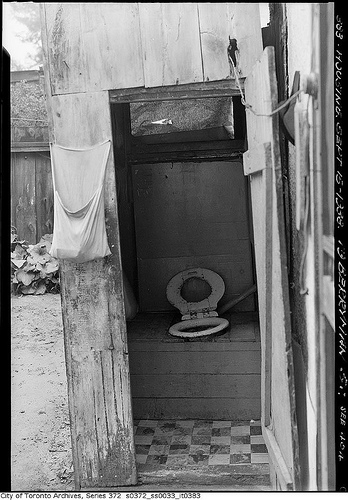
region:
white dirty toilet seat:
[157, 266, 236, 344]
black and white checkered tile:
[139, 416, 267, 469]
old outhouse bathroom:
[33, 4, 312, 490]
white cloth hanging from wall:
[43, 131, 128, 269]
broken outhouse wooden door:
[216, 42, 327, 484]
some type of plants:
[13, 235, 63, 298]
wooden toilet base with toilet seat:
[138, 308, 249, 428]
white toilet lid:
[163, 259, 231, 309]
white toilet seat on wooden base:
[164, 318, 236, 342]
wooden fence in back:
[11, 142, 56, 252]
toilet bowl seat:
[164, 269, 233, 341]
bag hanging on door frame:
[42, 130, 110, 261]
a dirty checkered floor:
[139, 415, 247, 452]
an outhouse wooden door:
[233, 48, 305, 483]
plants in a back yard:
[11, 231, 55, 293]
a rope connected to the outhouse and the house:
[223, 41, 310, 118]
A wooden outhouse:
[29, 6, 320, 496]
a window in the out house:
[125, 94, 236, 144]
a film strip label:
[333, 5, 342, 282]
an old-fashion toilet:
[129, 260, 263, 422]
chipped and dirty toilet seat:
[165, 266, 230, 338]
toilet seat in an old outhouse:
[164, 267, 226, 334]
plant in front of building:
[8, 227, 55, 294]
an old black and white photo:
[2, 3, 335, 490]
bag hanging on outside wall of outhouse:
[47, 136, 109, 260]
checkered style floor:
[132, 418, 267, 470]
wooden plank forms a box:
[134, 310, 258, 418]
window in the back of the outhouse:
[110, 94, 239, 137]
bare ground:
[9, 291, 71, 487]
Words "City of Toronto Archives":
[1, 490, 85, 497]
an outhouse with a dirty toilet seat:
[39, 159, 301, 384]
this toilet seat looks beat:
[157, 268, 238, 342]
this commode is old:
[77, 272, 320, 461]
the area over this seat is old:
[107, 71, 271, 168]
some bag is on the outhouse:
[35, 124, 136, 267]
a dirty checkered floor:
[123, 403, 296, 496]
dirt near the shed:
[13, 271, 77, 444]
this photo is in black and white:
[17, 198, 329, 433]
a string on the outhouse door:
[217, 48, 318, 117]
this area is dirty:
[13, 7, 318, 147]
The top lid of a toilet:
[164, 259, 228, 315]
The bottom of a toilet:
[165, 316, 239, 345]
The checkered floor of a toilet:
[134, 415, 271, 474]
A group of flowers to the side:
[9, 221, 64, 300]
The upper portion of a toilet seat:
[151, 267, 233, 316]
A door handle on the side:
[294, 65, 339, 494]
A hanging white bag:
[39, 129, 117, 270]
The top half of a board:
[64, 14, 145, 83]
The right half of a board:
[196, 0, 256, 78]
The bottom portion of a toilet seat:
[159, 314, 257, 347]